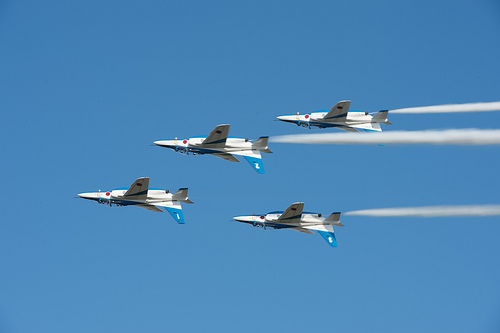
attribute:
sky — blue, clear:
[1, 0, 499, 332]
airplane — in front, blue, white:
[76, 176, 195, 225]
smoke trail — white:
[341, 203, 499, 219]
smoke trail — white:
[268, 127, 500, 146]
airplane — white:
[275, 98, 393, 133]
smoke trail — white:
[367, 100, 499, 116]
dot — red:
[104, 190, 112, 197]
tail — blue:
[153, 202, 187, 226]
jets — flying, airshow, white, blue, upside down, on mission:
[78, 99, 394, 249]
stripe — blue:
[123, 189, 148, 197]